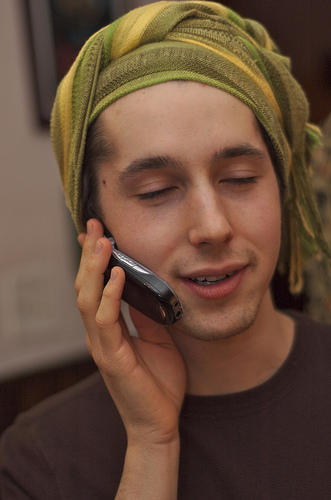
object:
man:
[0, 1, 330, 499]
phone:
[106, 236, 184, 324]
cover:
[49, 0, 331, 294]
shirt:
[0, 308, 330, 500]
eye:
[134, 181, 182, 203]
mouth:
[172, 260, 253, 301]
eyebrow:
[118, 154, 183, 182]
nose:
[188, 172, 234, 247]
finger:
[94, 265, 126, 357]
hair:
[81, 119, 116, 229]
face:
[88, 75, 282, 340]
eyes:
[217, 172, 261, 184]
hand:
[74, 218, 189, 443]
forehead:
[88, 80, 268, 161]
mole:
[101, 178, 106, 185]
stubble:
[175, 288, 271, 342]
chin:
[180, 306, 262, 341]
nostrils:
[194, 233, 237, 250]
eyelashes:
[135, 188, 168, 199]